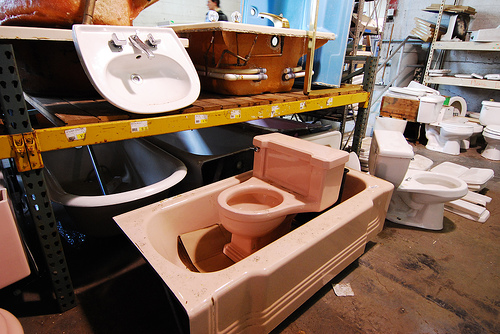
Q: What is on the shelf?
A: A white sink.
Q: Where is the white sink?
A: On a shelf.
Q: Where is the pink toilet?
A: In the bathtub.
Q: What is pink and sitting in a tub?
A: A toilet.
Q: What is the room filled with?
A: Bathroom fixtures.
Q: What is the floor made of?
A: Concrete.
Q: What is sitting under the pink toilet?
A: A tub.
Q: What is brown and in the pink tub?
A: Cardboard.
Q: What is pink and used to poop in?
A: A toilet.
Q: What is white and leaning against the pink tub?
A: A toilet.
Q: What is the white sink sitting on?
A: A shelf.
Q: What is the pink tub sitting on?
A: The floor.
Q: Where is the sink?
A: On the shelf.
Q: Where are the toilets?
A: On the ground.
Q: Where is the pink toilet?
A: In the tub.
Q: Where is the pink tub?
A: On the ground.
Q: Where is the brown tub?
A: On the shelf.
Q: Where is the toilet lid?
A: On the ground.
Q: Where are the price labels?
A: On the shelf.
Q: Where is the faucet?
A: On the sink.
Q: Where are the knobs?
A: On the sink.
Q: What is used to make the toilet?
A: Ceramic.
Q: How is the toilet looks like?
A: Pink.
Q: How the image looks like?
A: Ugly.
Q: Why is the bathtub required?
A: Take bath.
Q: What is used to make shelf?
A: Wood.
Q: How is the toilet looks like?
A: Tan.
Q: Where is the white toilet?
A: On ground.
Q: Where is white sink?
A: On shelf.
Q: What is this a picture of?
A: Bathroom fixtures.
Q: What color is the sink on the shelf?
A: White.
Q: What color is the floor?
A: Brown.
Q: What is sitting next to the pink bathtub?
A: Toilet.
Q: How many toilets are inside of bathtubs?
A: 1.